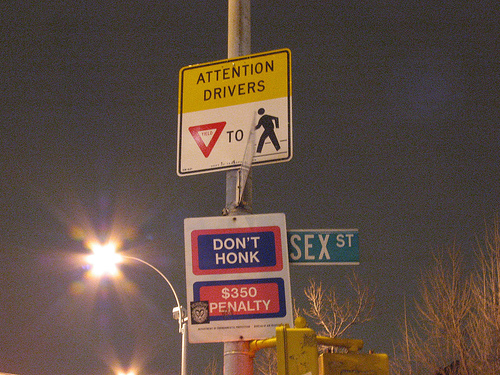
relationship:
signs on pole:
[175, 48, 312, 344] [222, 0, 257, 357]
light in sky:
[65, 219, 139, 288] [0, 1, 499, 374]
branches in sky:
[299, 258, 499, 374] [0, 1, 499, 374]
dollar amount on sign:
[218, 286, 261, 297] [183, 216, 293, 342]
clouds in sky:
[269, 2, 496, 249] [0, 1, 499, 374]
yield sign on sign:
[188, 124, 227, 157] [177, 48, 294, 170]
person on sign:
[252, 107, 284, 153] [177, 48, 294, 170]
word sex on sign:
[285, 230, 335, 262] [285, 225, 363, 268]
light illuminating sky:
[65, 219, 139, 288] [0, 1, 499, 374]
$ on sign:
[218, 285, 232, 300] [285, 225, 363, 268]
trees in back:
[299, 258, 499, 374] [283, 278, 495, 372]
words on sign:
[193, 58, 279, 100] [177, 48, 294, 170]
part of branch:
[306, 279, 323, 304] [300, 276, 336, 335]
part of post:
[242, 56, 290, 161] [177, 48, 294, 170]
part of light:
[95, 226, 131, 276] [65, 219, 139, 288]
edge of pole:
[243, 2, 253, 57] [222, 0, 257, 357]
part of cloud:
[129, 1, 192, 64] [1, 1, 208, 207]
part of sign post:
[242, 56, 290, 161] [177, 48, 294, 170]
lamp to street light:
[65, 219, 139, 288] [76, 228, 192, 374]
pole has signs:
[222, 0, 257, 357] [175, 48, 312, 344]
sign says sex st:
[285, 225, 363, 268] [288, 229, 354, 263]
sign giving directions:
[183, 216, 293, 342] [208, 235, 269, 266]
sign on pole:
[177, 48, 294, 170] [222, 0, 257, 357]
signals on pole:
[251, 320, 393, 373] [222, 0, 257, 357]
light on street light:
[65, 219, 139, 288] [76, 228, 192, 374]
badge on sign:
[190, 301, 209, 324] [183, 216, 293, 342]